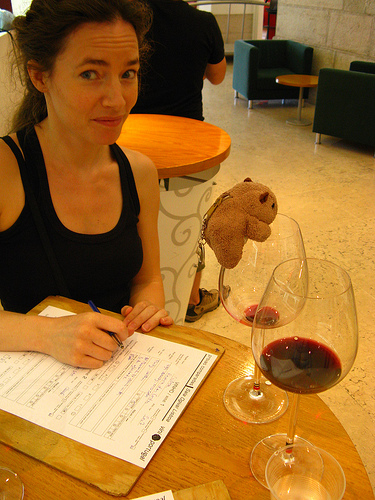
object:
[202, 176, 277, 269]
animal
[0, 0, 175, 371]
woman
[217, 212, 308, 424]
glass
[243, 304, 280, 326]
red wine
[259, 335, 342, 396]
red wine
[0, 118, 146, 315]
tank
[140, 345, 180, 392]
paper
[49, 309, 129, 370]
hand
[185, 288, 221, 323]
shoes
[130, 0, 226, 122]
man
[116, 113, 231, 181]
table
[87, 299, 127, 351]
pen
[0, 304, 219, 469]
application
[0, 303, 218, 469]
form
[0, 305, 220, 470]
writing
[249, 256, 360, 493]
wine glass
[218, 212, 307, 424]
wine glass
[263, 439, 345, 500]
plastic cup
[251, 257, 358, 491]
glass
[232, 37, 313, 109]
chair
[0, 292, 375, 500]
round table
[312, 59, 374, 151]
chair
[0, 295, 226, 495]
board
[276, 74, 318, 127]
table